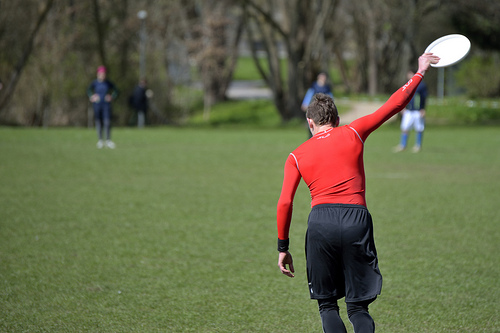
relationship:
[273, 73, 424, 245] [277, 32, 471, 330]
shirt on boy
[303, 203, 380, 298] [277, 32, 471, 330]
shorts on boy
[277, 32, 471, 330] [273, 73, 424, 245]
boy has on shirt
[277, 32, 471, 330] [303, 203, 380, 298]
boy has on shorts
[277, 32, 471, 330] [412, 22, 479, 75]
boy with frisbee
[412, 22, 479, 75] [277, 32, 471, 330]
frisbee with boy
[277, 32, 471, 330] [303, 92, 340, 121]
boy with hair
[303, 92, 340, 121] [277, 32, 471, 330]
hair on boy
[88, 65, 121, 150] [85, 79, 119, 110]
people has shirt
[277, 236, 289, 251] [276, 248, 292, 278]
wrist band on hand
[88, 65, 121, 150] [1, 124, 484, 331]
people on field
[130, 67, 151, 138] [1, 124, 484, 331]
people on field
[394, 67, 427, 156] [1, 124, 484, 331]
people on field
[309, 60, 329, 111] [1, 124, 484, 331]
people on field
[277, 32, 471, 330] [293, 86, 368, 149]
boy has hair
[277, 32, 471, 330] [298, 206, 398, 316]
boy wears shorts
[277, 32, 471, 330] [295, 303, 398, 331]
boy wears socks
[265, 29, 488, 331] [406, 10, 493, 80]
boy has frisbee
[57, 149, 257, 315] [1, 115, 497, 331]
field has grass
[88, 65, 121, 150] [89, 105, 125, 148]
people has jeans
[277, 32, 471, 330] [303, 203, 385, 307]
boy wears shorts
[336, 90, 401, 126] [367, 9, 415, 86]
pathway through tree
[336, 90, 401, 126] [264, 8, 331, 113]
pathway through tree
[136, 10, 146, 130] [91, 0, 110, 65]
light pole near tree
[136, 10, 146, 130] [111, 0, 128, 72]
light pole near tree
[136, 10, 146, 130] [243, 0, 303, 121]
light pole near tree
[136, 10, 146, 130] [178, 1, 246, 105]
light pole near tree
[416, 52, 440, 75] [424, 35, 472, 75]
male's hand has frisbee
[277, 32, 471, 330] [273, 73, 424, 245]
boy has shirt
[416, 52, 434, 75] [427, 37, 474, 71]
male's hand has frisbee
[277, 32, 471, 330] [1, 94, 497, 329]
boy on field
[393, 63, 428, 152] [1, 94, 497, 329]
people on field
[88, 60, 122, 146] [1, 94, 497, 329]
people on field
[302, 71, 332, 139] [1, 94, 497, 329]
people on field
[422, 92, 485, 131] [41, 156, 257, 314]
plants on field